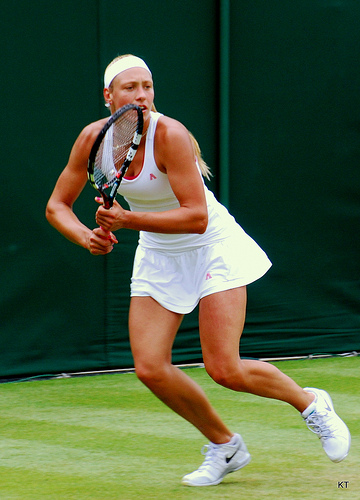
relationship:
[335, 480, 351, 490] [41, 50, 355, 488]
logo near woman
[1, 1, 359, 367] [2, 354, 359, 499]
wall behind court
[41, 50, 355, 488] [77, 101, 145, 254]
woman holding racket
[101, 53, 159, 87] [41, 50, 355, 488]
band on woman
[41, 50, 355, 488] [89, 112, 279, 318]
woman wearing outfit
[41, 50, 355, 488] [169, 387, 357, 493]
woman in shoes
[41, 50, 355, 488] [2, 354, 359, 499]
woman on court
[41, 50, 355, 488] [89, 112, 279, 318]
woman in outfit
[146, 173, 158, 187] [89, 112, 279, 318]
logo on outfit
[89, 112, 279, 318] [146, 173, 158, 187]
outfit has logo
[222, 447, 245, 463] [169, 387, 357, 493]
logo on shoes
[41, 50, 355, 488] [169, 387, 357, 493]
woman has shoes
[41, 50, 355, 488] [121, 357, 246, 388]
woman has knees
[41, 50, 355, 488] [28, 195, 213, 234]
woman has elbows